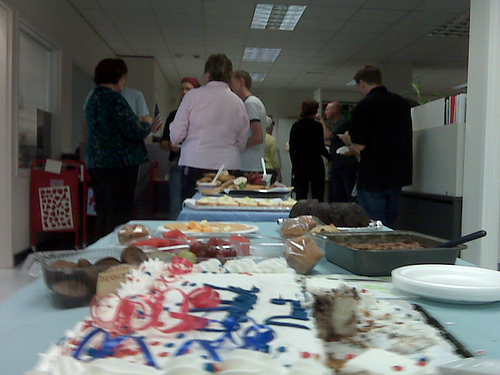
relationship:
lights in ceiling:
[247, 3, 303, 33] [70, 0, 468, 119]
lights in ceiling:
[245, 71, 265, 84] [70, 0, 468, 119]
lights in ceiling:
[240, 43, 281, 65] [70, 0, 468, 119]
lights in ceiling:
[427, 14, 466, 36] [70, 0, 468, 119]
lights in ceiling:
[345, 77, 356, 85] [70, 0, 468, 119]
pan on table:
[315, 224, 465, 276] [244, 204, 353, 286]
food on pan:
[347, 238, 424, 257] [315, 224, 465, 276]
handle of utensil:
[445, 228, 486, 246] [402, 214, 488, 266]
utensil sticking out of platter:
[402, 214, 488, 266] [319, 220, 469, 272]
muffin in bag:
[292, 230, 319, 269] [284, 227, 327, 277]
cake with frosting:
[23, 258, 473, 373] [28, 258, 328, 373]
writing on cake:
[263, 292, 311, 329] [23, 258, 473, 373]